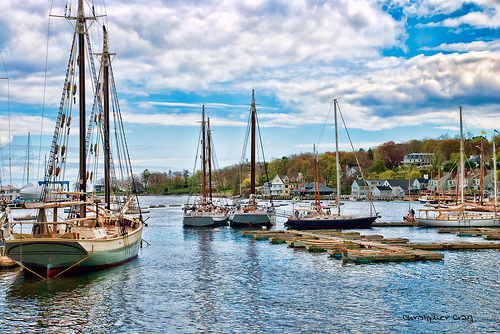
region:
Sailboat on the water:
[2, 0, 149, 286]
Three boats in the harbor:
[180, 89, 381, 236]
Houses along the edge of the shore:
[237, 174, 482, 199]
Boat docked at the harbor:
[406, 106, 498, 227]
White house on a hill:
[399, 145, 438, 170]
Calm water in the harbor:
[0, 194, 498, 329]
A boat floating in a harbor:
[10, 201, 144, 268]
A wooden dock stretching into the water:
[245, 225, 498, 265]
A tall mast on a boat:
[187, 107, 219, 208]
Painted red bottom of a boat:
[23, 257, 128, 277]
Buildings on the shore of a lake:
[352, 175, 405, 196]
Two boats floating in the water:
[185, 193, 275, 230]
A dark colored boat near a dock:
[284, 203, 376, 230]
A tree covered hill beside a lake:
[133, 140, 498, 190]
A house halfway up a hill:
[398, 151, 438, 164]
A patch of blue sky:
[402, 24, 445, 44]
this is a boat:
[4, 0, 144, 272]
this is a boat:
[182, 100, 230, 230]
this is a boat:
[232, 83, 280, 230]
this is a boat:
[280, 94, 381, 229]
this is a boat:
[400, 98, 499, 229]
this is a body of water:
[3, 279, 150, 329]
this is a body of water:
[147, 236, 228, 332]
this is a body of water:
[254, 235, 331, 332]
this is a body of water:
[363, 269, 493, 326]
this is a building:
[342, 158, 426, 200]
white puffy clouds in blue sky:
[0, 1, 498, 183]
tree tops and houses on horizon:
[104, 136, 496, 196]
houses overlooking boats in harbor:
[0, 0, 498, 332]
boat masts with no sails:
[2, 2, 499, 281]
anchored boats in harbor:
[0, 1, 497, 278]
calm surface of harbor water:
[1, 196, 497, 331]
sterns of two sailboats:
[180, 90, 275, 227]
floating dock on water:
[243, 227, 498, 265]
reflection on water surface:
[5, 261, 132, 331]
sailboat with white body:
[415, 106, 498, 227]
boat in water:
[35, 208, 149, 280]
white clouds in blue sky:
[380, 65, 405, 112]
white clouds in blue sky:
[285, 39, 316, 80]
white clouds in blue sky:
[154, 33, 188, 90]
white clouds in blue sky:
[125, 23, 163, 60]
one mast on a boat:
[328, 96, 350, 213]